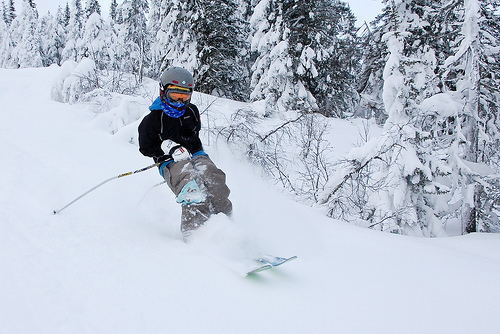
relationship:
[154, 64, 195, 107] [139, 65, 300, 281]
helmet on skier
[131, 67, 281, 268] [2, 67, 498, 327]
guy down hill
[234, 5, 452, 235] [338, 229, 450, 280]
trees on snow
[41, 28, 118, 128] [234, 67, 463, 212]
snow on bushes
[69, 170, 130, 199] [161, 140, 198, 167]
ski pole in skier's hand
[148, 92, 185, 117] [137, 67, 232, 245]
bandana on guy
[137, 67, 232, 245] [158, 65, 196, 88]
guy wearing helmet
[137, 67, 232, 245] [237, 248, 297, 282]
guy wearing skis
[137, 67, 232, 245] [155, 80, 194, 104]
guy wearing goggles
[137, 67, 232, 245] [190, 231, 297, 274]
guy on skateboard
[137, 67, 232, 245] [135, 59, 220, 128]
guy wearing helmet